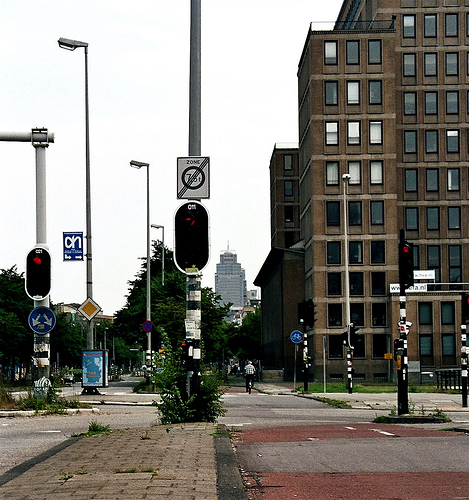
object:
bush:
[146, 328, 227, 425]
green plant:
[151, 365, 231, 427]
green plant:
[12, 375, 87, 419]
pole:
[146, 164, 151, 378]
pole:
[161, 229, 165, 292]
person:
[244, 360, 257, 392]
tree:
[118, 244, 241, 393]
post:
[398, 290, 406, 413]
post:
[303, 329, 309, 392]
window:
[323, 39, 337, 65]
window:
[345, 40, 357, 65]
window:
[366, 40, 382, 65]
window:
[345, 82, 358, 106]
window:
[324, 80, 337, 106]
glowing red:
[33, 257, 43, 265]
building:
[213, 244, 245, 326]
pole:
[185, 0, 202, 385]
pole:
[35, 125, 48, 396]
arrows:
[32, 313, 42, 327]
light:
[52, 34, 89, 50]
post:
[82, 53, 93, 395]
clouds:
[8, 10, 263, 297]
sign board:
[388, 282, 426, 293]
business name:
[390, 285, 434, 293]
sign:
[26, 306, 54, 336]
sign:
[77, 298, 102, 324]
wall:
[214, 251, 244, 310]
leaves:
[6, 278, 26, 295]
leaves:
[125, 301, 135, 319]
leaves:
[213, 313, 221, 333]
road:
[0, 372, 469, 499]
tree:
[151, 329, 218, 424]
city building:
[257, 0, 469, 389]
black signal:
[398, 239, 415, 291]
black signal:
[298, 303, 305, 325]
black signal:
[174, 203, 208, 271]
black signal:
[25, 245, 51, 297]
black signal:
[461, 288, 468, 322]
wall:
[273, 0, 465, 354]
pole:
[293, 344, 297, 391]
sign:
[290, 329, 305, 344]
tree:
[1, 263, 32, 379]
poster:
[185, 311, 200, 340]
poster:
[194, 347, 202, 361]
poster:
[185, 345, 193, 356]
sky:
[2, 5, 343, 309]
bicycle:
[244, 372, 256, 394]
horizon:
[7, 298, 284, 309]